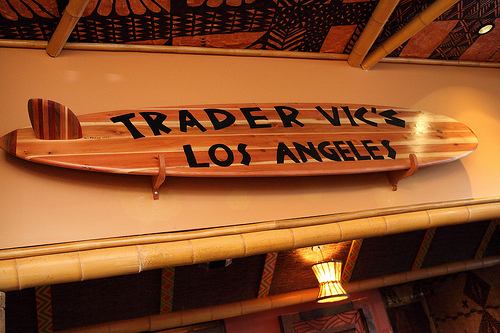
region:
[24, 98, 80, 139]
striped tail fin on the surfboard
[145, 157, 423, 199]
brackets holding surfboard on the wall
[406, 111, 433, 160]
glare of light on the surfboard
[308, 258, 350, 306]
light fixture attached to the ceiling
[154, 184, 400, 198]
bolts holding brackets on the wall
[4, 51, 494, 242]
light brown wall the surfboard is on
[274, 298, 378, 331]
framed artwork on the wall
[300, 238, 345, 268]
light from the light fixture on the ceiling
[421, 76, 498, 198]
light reflection on the wall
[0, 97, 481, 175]
A brown surfboard with black words on it.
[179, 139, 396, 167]
The city Los Angeles on a surfboard.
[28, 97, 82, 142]
Back fin of a brown surfboard.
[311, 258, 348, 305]
An illuminated light under the surfboard.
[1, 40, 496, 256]
A tan wall behind a surfboard.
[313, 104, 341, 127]
Black V in VIC'S.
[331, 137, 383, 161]
Black ELE in ANGELES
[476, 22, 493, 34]
Round white illuminated light in the ceiling.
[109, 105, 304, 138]
Black TRADER on a surfboard.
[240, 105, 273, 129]
Large black E in TRADER.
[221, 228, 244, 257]
part f a line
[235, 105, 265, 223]
part of a leter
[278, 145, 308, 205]
part fo a letter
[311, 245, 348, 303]
the light hanging from the ceiling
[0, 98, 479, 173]
the surfboard on the wall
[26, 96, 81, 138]
the fin on the surfboard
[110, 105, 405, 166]
the words on the surfboard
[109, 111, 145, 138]
the letter "T" on the surfboard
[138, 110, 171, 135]
the letter "R" on the surfboard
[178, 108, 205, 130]
the letter "A" on the surfboard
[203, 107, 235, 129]
the letter "D" on the surfboard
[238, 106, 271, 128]
the letter "E" on the surfboard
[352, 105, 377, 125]
the letter "C" on the surfboard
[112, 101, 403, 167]
the text is black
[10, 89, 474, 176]
board made of wood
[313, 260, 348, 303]
light on the ceiling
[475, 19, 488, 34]
light on the ceiling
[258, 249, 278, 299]
a squiggly line design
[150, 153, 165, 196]
the base is wood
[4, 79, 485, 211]
a wooden surfboard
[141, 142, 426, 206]
a couple of wood brackets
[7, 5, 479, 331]
a scene inside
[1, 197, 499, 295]
a strip of bamboo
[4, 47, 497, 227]
a white wall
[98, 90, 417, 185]
TRADER VIC'S LOS ANGELES on a surfboard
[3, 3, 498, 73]
a festive ceiling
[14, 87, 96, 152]
a fin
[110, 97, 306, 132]
the black word trader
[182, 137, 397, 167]
the black word los angeles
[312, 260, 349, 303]
the bright lit light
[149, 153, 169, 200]
the wooden hanger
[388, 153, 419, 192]
the wooden hanger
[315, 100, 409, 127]
the black word vic's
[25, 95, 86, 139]
the wooden rudder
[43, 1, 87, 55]
the bamboo pole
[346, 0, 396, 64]
the bamboo pole